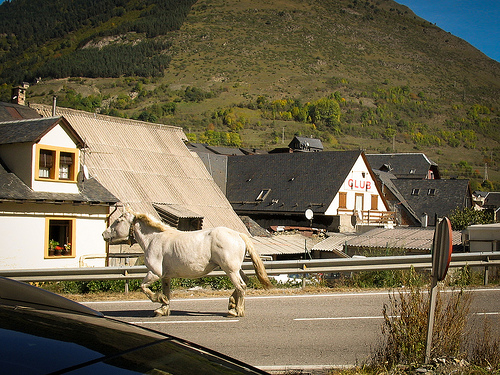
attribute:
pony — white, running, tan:
[102, 200, 273, 320]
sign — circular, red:
[429, 217, 454, 287]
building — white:
[0, 79, 122, 270]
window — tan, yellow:
[47, 219, 73, 257]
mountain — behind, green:
[2, 2, 500, 194]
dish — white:
[301, 207, 315, 219]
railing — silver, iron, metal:
[0, 250, 497, 283]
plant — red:
[56, 242, 65, 250]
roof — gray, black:
[225, 148, 361, 213]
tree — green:
[315, 99, 342, 128]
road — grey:
[77, 286, 498, 369]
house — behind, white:
[196, 154, 395, 228]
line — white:
[81, 285, 497, 308]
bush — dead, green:
[371, 266, 476, 368]